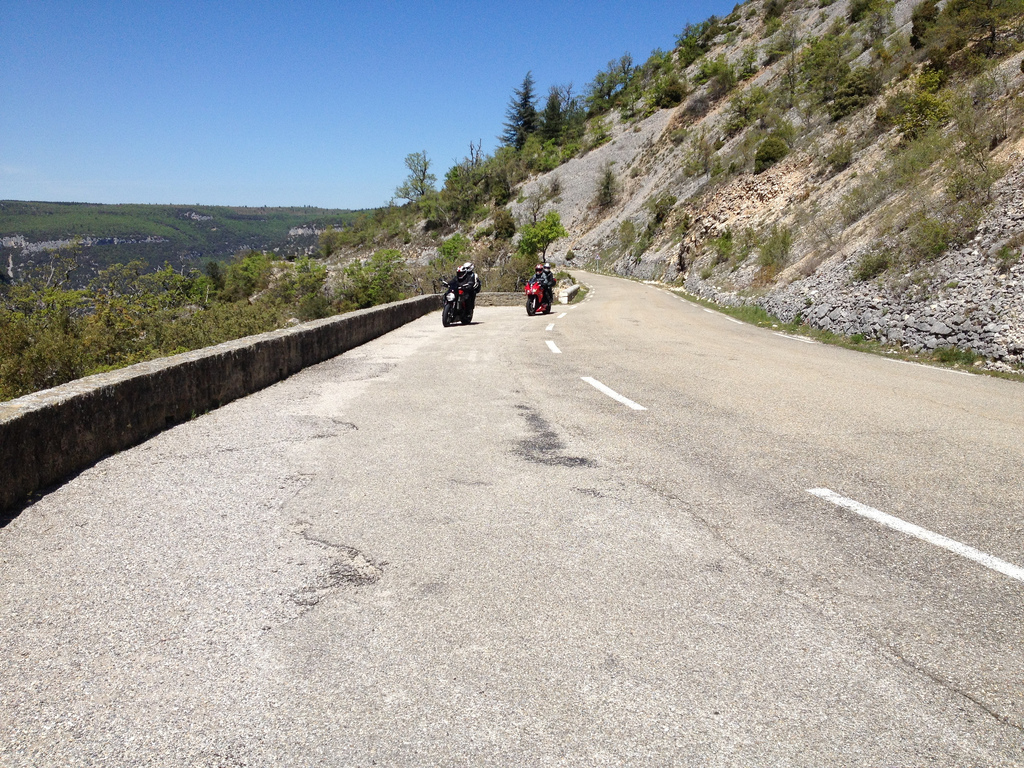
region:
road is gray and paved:
[3, 263, 1022, 766]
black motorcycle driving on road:
[9, 256, 1021, 766]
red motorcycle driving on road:
[3, 265, 1022, 766]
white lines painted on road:
[5, 268, 1021, 763]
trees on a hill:
[420, 3, 1021, 376]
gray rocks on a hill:
[398, 0, 1022, 380]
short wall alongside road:
[0, 266, 1022, 761]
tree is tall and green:
[492, 62, 546, 161]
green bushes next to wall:
[2, 278, 451, 525]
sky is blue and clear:
[0, 2, 744, 212]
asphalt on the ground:
[826, 566, 884, 601]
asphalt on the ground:
[863, 420, 870, 422]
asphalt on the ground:
[694, 499, 711, 523]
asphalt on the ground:
[201, 546, 224, 569]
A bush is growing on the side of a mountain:
[702, 225, 761, 265]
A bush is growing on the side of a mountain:
[852, 239, 894, 284]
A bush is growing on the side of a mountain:
[653, 60, 689, 108]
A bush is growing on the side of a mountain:
[596, 157, 619, 214]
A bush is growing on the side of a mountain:
[529, 130, 567, 170]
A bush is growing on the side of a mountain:
[696, 50, 739, 92]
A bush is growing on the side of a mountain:
[678, 21, 710, 59]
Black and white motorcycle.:
[441, 256, 483, 327]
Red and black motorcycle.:
[515, 255, 551, 322]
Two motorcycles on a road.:
[430, 234, 563, 329]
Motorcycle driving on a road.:
[443, 250, 479, 339]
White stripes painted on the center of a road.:
[529, 280, 1020, 634]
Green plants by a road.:
[6, 174, 475, 383]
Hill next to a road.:
[501, 37, 1017, 335]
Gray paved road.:
[0, 168, 1022, 757]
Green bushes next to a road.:
[104, 243, 444, 355]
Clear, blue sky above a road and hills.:
[8, 1, 694, 207]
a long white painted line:
[582, 370, 655, 416]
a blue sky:
[4, 2, 447, 202]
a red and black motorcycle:
[520, 279, 553, 314]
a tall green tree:
[501, 76, 540, 147]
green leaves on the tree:
[640, 48, 675, 106]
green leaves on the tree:
[552, 113, 595, 156]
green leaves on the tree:
[491, 89, 555, 185]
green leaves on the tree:
[424, 142, 476, 203]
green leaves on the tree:
[152, 259, 230, 337]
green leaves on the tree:
[105, 276, 128, 352]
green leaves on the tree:
[140, 276, 195, 328]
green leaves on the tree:
[125, 241, 221, 319]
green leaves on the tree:
[70, 329, 102, 352]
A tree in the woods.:
[600, 163, 624, 203]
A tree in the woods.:
[751, 130, 796, 170]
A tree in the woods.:
[505, 67, 548, 153]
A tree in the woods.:
[389, 149, 441, 204]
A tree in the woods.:
[318, 220, 351, 262]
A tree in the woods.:
[223, 257, 258, 286]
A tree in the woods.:
[201, 258, 228, 293]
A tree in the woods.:
[331, 258, 396, 306]